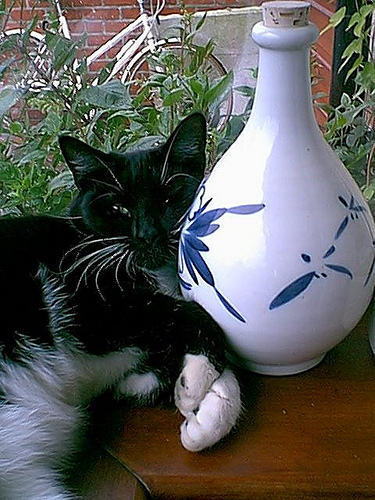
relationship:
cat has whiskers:
[0, 109, 242, 499] [59, 235, 134, 296]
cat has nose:
[58, 117, 210, 259] [134, 224, 162, 241]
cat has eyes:
[0, 109, 242, 499] [107, 198, 174, 212]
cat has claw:
[0, 109, 242, 499] [173, 352, 223, 417]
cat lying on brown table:
[0, 109, 242, 499] [70, 312, 374, 498]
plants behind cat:
[1, 0, 236, 217] [0, 109, 242, 499]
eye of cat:
[111, 200, 135, 220] [0, 109, 242, 499]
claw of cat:
[168, 352, 241, 456] [34, 125, 187, 282]